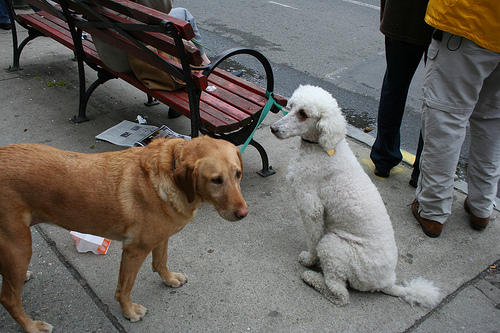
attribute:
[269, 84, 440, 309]
poodle — white, sitting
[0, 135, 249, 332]
retriever — golden, brown, tan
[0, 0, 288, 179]
bench — black, red, brown, bolted down, wood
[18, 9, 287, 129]
seat — red, wooden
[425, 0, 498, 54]
windbreaker — yellow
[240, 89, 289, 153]
leash — green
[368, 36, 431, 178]
jeans — blue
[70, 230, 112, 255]
paper — orange, white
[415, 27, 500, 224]
pants — gray, cargo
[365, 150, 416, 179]
streak — yellow